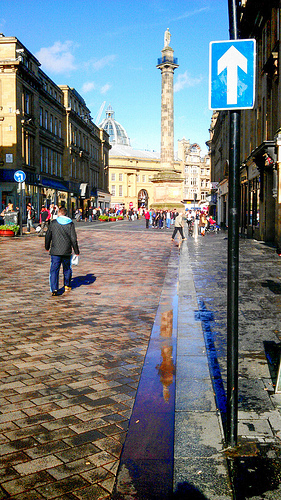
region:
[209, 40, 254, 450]
Directional sign secured on pole in sidewalk.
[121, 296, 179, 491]
Puddle of water from recent rain.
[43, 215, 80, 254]
Person wearing black quilted jacket with blue hood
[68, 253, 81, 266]
Person carrying white bag in right hand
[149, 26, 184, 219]
Beautiful, tall monument in open square.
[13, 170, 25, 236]
Left turn directional sign on post.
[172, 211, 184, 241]
Person stepping over puddle of water.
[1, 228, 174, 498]
Cobblestone/brick paved street.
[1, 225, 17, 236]
Container of greenery/flowers on corner.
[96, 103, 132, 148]
Beautiful tall glass dome of church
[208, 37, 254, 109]
blue and white sign with an arrow pointing up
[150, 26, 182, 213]
large tower with a statue on top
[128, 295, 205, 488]
water puddle on stone pavement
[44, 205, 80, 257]
man wearing a black jacket with a diamond pattern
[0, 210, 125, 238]
large planters with green plants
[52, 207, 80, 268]
man holding a bag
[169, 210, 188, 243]
man taking a big step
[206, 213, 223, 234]
person in a wheelchair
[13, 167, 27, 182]
round blue and white sign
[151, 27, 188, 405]
reflection of tower in puddle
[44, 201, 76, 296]
man in a black jacket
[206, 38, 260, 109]
blue sign with white arrow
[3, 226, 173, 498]
road paved with bricks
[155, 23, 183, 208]
white tower with a sculpture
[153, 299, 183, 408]
reflection of tower and sculpture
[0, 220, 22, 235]
red planters along street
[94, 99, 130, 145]
white and glass dome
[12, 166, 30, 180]
blue sign with left arrow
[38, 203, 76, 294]
man wearing blue pants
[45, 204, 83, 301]
man with dark hair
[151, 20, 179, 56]
A statue above the buildings.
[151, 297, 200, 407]
Reflection of a statue in the water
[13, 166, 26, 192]
A blue traffic sign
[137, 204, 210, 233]
Many people moving along the street.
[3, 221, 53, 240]
A planter full of vegetation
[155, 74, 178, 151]
A old, white pillar.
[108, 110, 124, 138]
A glass dome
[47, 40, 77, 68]
White clouds in the background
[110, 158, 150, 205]
A yellow-colored building.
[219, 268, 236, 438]
A black metal beam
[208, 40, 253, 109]
Upward pointing white arrow on blue sign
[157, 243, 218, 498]
wet, soggy trough in curb of street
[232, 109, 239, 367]
black sign post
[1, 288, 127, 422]
interlocked brick street pattern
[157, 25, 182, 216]
Tower monument with statue on tip in distance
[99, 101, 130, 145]
Glass-domed building top.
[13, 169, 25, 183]
Round, blue sign with, left-pointing white arrow.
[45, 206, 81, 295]
Man walkin on brick steet looking left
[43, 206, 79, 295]
Man carrying medium-sized white bag in right hand.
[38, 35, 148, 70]
Whispy, white clouds in clear, blue sky.